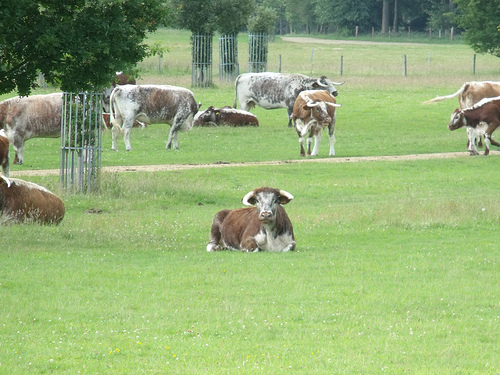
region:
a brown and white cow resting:
[207, 184, 298, 251]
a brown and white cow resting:
[195, 106, 260, 128]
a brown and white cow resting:
[0, 172, 63, 226]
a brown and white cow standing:
[290, 87, 340, 156]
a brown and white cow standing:
[447, 94, 498, 156]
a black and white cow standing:
[232, 70, 345, 128]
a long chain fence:
[145, 48, 496, 76]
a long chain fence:
[271, 21, 471, 40]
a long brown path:
[2, 149, 499, 176]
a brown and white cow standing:
[0, 90, 66, 165]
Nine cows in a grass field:
[0, 15, 495, 301]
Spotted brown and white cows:
[190, 37, 380, 122]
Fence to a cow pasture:
[132, 15, 494, 100]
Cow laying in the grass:
[184, 90, 274, 141]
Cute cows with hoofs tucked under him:
[181, 167, 338, 284]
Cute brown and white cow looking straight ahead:
[139, 167, 347, 331]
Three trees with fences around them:
[166, 7, 275, 89]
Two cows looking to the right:
[262, 50, 407, 192]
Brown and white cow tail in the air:
[388, 65, 490, 116]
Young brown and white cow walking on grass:
[361, 101, 498, 194]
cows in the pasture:
[8, 64, 499, 269]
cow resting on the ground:
[203, 190, 306, 252]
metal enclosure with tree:
[50, 82, 110, 184]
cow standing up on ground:
[287, 89, 350, 148]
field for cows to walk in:
[20, 175, 474, 360]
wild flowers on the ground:
[109, 215, 189, 246]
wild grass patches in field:
[348, 190, 482, 220]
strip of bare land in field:
[12, 148, 487, 181]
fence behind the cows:
[148, 46, 498, 78]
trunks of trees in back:
[371, 3, 408, 36]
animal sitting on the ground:
[203, 189, 315, 260]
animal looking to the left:
[296, 101, 374, 156]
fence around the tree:
[60, 93, 110, 205]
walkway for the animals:
[106, 146, 443, 191]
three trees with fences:
[176, 17, 281, 69]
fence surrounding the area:
[294, 46, 486, 72]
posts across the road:
[313, 25, 459, 38]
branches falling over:
[1, 10, 143, 102]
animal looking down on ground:
[78, 73, 218, 148]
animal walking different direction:
[456, 112, 499, 152]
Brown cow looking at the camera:
[203, 184, 300, 256]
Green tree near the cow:
[0, 0, 165, 192]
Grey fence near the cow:
[141, 50, 498, 79]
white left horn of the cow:
[241, 187, 259, 207]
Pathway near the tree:
[0, 146, 497, 181]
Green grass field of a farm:
[0, 26, 499, 374]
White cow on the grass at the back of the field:
[233, 71, 344, 129]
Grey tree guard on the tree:
[60, 89, 106, 198]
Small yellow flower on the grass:
[102, 336, 192, 364]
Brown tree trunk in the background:
[377, 0, 391, 37]